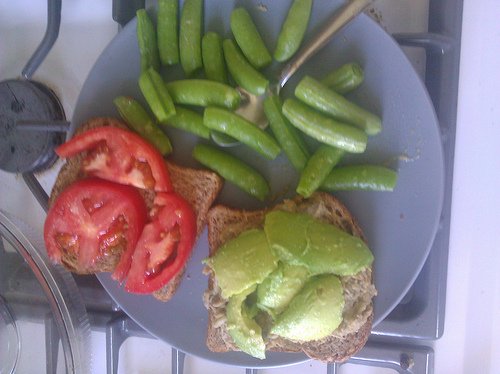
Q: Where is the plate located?
A: On the stove.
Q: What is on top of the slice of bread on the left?
A: Tomatoes.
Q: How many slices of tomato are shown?
A: Three.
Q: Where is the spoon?
A: On the plate under the beans.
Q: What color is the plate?
A: Slate blue.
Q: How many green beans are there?
A: Nineteen.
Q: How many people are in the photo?
A: None.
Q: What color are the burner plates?
A: Grey.